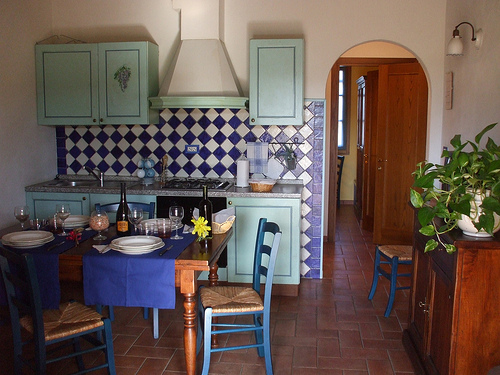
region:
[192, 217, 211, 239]
the flower is yellow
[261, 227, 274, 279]
the chair is blue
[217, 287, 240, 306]
the seat is tan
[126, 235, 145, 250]
the plate is white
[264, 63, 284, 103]
the cabinet is pale blue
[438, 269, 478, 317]
the stand is brown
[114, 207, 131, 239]
the bottle is on the table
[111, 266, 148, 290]
the table mat is blue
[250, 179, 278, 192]
the basket is on the counter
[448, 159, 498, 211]
the plant is in the pot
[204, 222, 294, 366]
the chair is blue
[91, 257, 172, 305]
the table clothe is blue in color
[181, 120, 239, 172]
the wall is blue and white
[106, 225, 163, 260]
the plates are two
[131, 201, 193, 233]
glases are on the table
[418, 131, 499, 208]
flowers are on the pot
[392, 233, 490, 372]
the cabinet is wooden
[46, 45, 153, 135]
the cabinets are blue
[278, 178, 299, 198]
the counter is marbled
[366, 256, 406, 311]
the legs are blue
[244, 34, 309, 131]
A teal cabinet on the wall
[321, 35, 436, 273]
A arched walkway to enter another room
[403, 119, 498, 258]
A green potted plant in a white vase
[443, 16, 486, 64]
A white light fixture attached to the wall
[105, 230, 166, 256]
A white plate sitting on the table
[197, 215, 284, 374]
A blue chair at the table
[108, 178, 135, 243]
A bottle of wine on the table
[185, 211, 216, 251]
A yellow flower on the table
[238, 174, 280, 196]
A brown basket on the counter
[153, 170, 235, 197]
A stainless steel oven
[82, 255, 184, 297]
the table clothe is blue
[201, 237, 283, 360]
the chair is wooden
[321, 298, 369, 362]
the floor has tiles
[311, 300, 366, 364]
the tiles are brown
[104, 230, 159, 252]
the plates are white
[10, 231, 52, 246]
the plats are white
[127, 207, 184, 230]
wine glasses are two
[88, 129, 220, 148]
the wall is blue and white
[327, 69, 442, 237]
the door is open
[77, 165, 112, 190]
the tap is silver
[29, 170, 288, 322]
view at a dinning table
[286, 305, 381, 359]
floor is brown in color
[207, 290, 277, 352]
the seat is blue in color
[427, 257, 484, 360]
the cupboard is wooden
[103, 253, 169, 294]
the table mat is blue in color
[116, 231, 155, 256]
the plates are white in color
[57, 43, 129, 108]
the drawers are light blue inc color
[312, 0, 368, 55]
the wall is light pink in color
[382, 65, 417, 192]
the doors are brown in color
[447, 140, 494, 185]
the flower is green in color